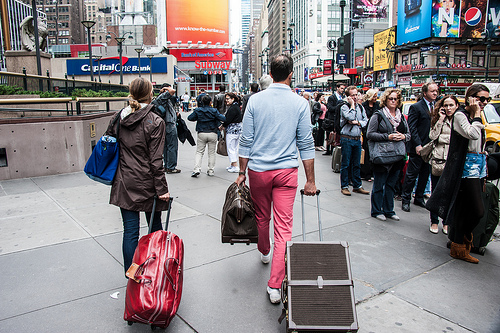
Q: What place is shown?
A: It is a sidewalk.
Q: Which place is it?
A: It is a sidewalk.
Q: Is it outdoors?
A: Yes, it is outdoors.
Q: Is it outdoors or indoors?
A: It is outdoors.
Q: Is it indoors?
A: No, it is outdoors.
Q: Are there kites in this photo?
A: No, there are no kites.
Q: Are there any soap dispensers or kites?
A: No, there are no kites or soap dispensers.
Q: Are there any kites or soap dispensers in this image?
A: No, there are no kites or soap dispensers.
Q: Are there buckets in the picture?
A: No, there are no buckets.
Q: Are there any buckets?
A: No, there are no buckets.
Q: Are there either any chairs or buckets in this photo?
A: No, there are no buckets or chairs.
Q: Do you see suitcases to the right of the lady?
A: Yes, there is a suitcase to the right of the lady.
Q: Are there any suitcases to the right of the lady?
A: Yes, there is a suitcase to the right of the lady.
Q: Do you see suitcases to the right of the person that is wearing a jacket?
A: Yes, there is a suitcase to the right of the lady.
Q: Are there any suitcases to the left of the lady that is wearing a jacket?
A: No, the suitcase is to the right of the lady.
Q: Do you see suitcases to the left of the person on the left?
A: No, the suitcase is to the right of the lady.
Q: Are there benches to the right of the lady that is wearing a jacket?
A: No, there is a suitcase to the right of the lady.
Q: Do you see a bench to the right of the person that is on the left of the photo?
A: No, there is a suitcase to the right of the lady.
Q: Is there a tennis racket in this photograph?
A: No, there are no rackets.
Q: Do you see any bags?
A: Yes, there is a bag.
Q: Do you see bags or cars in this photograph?
A: Yes, there is a bag.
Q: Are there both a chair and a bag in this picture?
A: No, there is a bag but no chairs.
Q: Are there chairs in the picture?
A: No, there are no chairs.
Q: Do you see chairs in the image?
A: No, there are no chairs.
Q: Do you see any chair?
A: No, there are no chairs.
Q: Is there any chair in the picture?
A: No, there are no chairs.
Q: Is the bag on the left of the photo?
A: Yes, the bag is on the left of the image.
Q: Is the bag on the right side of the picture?
A: No, the bag is on the left of the image.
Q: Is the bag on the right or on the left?
A: The bag is on the left of the image.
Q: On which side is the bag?
A: The bag is on the left of the image.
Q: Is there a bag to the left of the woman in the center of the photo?
A: Yes, there is a bag to the left of the woman.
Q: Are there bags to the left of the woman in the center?
A: Yes, there is a bag to the left of the woman.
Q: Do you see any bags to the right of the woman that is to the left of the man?
A: No, the bag is to the left of the woman.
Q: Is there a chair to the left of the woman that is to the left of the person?
A: No, there is a bag to the left of the woman.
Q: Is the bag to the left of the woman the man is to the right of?
A: Yes, the bag is to the left of the woman.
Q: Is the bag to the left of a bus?
A: No, the bag is to the left of the woman.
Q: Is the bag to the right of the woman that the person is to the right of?
A: No, the bag is to the left of the woman.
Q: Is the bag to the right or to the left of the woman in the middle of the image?
A: The bag is to the left of the woman.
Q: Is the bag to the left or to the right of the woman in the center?
A: The bag is to the left of the woman.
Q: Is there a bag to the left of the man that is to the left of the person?
A: Yes, there is a bag to the left of the man.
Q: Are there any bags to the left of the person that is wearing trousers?
A: Yes, there is a bag to the left of the man.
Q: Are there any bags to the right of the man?
A: No, the bag is to the left of the man.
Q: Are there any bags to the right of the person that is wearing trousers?
A: No, the bag is to the left of the man.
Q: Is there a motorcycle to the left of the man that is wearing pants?
A: No, there is a bag to the left of the man.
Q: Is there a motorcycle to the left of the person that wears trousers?
A: No, there is a bag to the left of the man.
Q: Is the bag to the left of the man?
A: Yes, the bag is to the left of the man.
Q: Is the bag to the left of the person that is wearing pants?
A: Yes, the bag is to the left of the man.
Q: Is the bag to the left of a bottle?
A: No, the bag is to the left of the man.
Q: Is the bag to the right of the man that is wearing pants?
A: No, the bag is to the left of the man.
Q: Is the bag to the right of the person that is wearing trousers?
A: No, the bag is to the left of the man.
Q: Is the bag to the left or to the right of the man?
A: The bag is to the left of the man.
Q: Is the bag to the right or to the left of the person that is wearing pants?
A: The bag is to the left of the man.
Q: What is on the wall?
A: The sign is on the wall.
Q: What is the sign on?
A: The sign is on the wall.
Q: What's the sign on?
A: The sign is on the wall.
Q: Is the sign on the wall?
A: Yes, the sign is on the wall.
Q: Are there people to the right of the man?
A: Yes, there is a person to the right of the man.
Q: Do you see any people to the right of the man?
A: Yes, there is a person to the right of the man.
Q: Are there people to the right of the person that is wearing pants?
A: Yes, there is a person to the right of the man.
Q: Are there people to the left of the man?
A: No, the person is to the right of the man.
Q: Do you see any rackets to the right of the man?
A: No, there is a person to the right of the man.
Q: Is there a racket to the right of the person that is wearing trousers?
A: No, there is a person to the right of the man.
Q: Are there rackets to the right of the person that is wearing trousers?
A: No, there is a person to the right of the man.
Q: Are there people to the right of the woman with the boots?
A: No, the person is to the left of the woman.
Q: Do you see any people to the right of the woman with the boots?
A: No, the person is to the left of the woman.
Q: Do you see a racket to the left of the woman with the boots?
A: No, there is a person to the left of the woman.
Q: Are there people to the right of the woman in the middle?
A: Yes, there is a person to the right of the woman.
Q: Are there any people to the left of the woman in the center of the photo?
A: No, the person is to the right of the woman.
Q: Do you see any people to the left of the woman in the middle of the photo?
A: No, the person is to the right of the woman.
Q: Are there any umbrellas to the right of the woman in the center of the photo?
A: No, there is a person to the right of the woman.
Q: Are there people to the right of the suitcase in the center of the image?
A: Yes, there is a person to the right of the suitcase.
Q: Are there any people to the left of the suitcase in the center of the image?
A: No, the person is to the right of the suitcase.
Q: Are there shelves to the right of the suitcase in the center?
A: No, there is a person to the right of the suitcase.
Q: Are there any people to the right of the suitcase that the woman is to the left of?
A: Yes, there is a person to the right of the suitcase.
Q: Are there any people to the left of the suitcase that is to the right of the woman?
A: No, the person is to the right of the suitcase.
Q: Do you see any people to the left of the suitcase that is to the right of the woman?
A: No, the person is to the right of the suitcase.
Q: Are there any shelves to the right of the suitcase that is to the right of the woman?
A: No, there is a person to the right of the suitcase.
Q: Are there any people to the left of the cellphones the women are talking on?
A: Yes, there is a person to the left of the mobile phones.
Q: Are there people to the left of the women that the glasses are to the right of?
A: Yes, there is a person to the left of the women.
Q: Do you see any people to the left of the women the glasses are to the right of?
A: Yes, there is a person to the left of the women.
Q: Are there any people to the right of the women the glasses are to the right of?
A: No, the person is to the left of the women.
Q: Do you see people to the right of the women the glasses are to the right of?
A: No, the person is to the left of the women.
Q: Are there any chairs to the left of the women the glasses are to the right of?
A: No, there is a person to the left of the women.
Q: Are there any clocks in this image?
A: No, there are no clocks.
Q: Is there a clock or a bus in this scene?
A: No, there are no clocks or buses.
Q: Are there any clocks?
A: No, there are no clocks.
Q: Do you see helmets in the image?
A: No, there are no helmets.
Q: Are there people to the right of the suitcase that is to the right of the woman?
A: Yes, there is a person to the right of the suitcase.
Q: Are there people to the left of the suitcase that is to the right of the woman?
A: No, the person is to the right of the suitcase.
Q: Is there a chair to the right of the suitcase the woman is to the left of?
A: No, there is a person to the right of the suitcase.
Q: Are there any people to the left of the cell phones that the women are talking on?
A: Yes, there is a person to the left of the mobile phones.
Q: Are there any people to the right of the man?
A: Yes, there is a person to the right of the man.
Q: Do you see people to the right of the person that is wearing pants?
A: Yes, there is a person to the right of the man.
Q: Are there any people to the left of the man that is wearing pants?
A: No, the person is to the right of the man.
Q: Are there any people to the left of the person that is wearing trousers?
A: No, the person is to the right of the man.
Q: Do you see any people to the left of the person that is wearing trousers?
A: No, the person is to the right of the man.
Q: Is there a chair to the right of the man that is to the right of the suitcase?
A: No, there is a person to the right of the man.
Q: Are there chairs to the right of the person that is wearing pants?
A: No, there is a person to the right of the man.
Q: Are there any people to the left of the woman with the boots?
A: Yes, there is a person to the left of the woman.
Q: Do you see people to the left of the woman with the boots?
A: Yes, there is a person to the left of the woman.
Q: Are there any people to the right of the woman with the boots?
A: No, the person is to the left of the woman.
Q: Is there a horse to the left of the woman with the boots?
A: No, there is a person to the left of the woman.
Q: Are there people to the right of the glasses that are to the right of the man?
A: Yes, there is a person to the right of the glasses.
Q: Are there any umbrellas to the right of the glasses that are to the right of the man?
A: No, there is a person to the right of the glasses.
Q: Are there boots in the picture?
A: Yes, there are boots.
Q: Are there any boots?
A: Yes, there are boots.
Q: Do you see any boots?
A: Yes, there are boots.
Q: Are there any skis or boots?
A: Yes, there are boots.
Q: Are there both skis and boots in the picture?
A: No, there are boots but no skis.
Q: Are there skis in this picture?
A: No, there are no skis.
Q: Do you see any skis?
A: No, there are no skis.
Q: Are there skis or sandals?
A: No, there are no skis or sandals.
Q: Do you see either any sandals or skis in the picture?
A: No, there are no skis or sandals.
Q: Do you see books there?
A: No, there are no books.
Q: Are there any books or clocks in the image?
A: No, there are no books or clocks.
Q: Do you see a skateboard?
A: No, there are no skateboards.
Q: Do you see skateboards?
A: No, there are no skateboards.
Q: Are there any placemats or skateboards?
A: No, there are no skateboards or placemats.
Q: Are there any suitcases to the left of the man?
A: Yes, there is a suitcase to the left of the man.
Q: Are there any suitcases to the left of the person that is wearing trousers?
A: Yes, there is a suitcase to the left of the man.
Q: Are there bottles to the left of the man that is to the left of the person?
A: No, there is a suitcase to the left of the man.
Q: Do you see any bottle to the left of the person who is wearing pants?
A: No, there is a suitcase to the left of the man.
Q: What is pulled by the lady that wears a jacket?
A: The suitcase is pulled by the lady.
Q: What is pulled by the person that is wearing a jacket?
A: The suitcase is pulled by the lady.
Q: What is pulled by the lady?
A: The suitcase is pulled by the lady.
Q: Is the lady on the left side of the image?
A: Yes, the lady is on the left of the image.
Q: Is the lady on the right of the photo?
A: No, the lady is on the left of the image.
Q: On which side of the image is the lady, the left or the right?
A: The lady is on the left of the image.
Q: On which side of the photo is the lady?
A: The lady is on the left of the image.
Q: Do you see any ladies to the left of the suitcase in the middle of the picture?
A: Yes, there is a lady to the left of the suitcase.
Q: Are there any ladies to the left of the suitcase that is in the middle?
A: Yes, there is a lady to the left of the suitcase.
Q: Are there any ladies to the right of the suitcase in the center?
A: No, the lady is to the left of the suitcase.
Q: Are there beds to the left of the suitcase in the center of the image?
A: No, there is a lady to the left of the suitcase.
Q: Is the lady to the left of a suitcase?
A: Yes, the lady is to the left of a suitcase.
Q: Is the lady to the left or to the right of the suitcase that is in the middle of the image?
A: The lady is to the left of the suitcase.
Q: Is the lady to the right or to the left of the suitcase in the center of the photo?
A: The lady is to the left of the suitcase.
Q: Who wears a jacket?
A: The lady wears a jacket.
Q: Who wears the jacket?
A: The lady wears a jacket.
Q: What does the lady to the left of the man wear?
A: The lady wears a jacket.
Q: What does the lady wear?
A: The lady wears a jacket.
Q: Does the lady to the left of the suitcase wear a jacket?
A: Yes, the lady wears a jacket.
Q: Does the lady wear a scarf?
A: No, the lady wears a jacket.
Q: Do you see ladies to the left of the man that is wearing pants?
A: Yes, there is a lady to the left of the man.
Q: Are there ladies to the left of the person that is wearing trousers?
A: Yes, there is a lady to the left of the man.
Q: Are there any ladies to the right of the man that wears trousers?
A: No, the lady is to the left of the man.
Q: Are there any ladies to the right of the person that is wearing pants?
A: No, the lady is to the left of the man.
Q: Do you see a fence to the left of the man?
A: No, there is a lady to the left of the man.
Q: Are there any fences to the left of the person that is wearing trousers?
A: No, there is a lady to the left of the man.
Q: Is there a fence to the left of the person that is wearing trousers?
A: No, there is a lady to the left of the man.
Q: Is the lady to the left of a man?
A: Yes, the lady is to the left of a man.